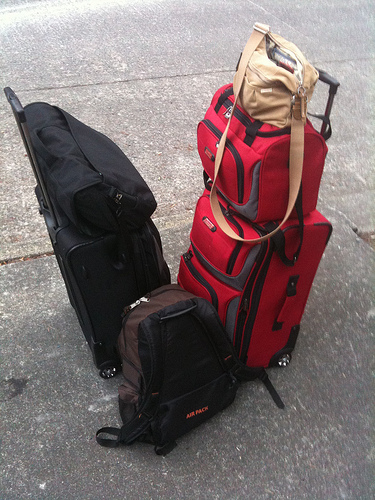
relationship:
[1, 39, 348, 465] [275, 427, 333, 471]
luggage on sidewalk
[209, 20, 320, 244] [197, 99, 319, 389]
bag on luggage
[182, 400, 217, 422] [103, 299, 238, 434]
logo on backpack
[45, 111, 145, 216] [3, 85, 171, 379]
bag on luggage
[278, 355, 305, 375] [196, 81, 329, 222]
wheel on bag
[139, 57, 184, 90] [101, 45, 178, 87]
crack in sidewalk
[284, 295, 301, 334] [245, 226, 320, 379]
handle on bag